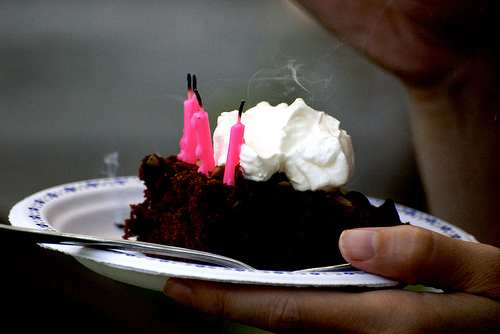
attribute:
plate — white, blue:
[9, 173, 133, 240]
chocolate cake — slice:
[133, 153, 393, 266]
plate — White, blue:
[6, 167, 477, 287]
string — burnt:
[234, 97, 249, 119]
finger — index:
[163, 270, 465, 332]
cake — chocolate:
[112, 67, 414, 274]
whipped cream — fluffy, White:
[213, 95, 358, 191]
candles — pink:
[179, 58, 251, 207]